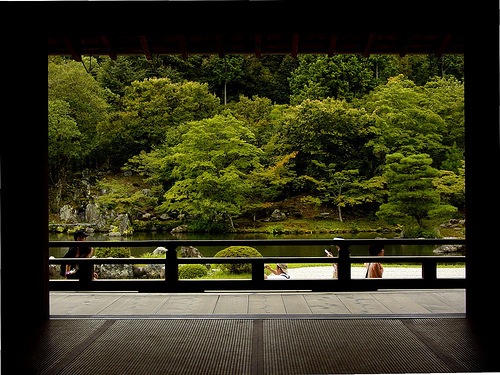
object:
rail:
[50, 239, 465, 294]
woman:
[365, 242, 386, 279]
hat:
[333, 236, 346, 241]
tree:
[122, 109, 297, 235]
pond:
[49, 231, 463, 266]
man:
[327, 236, 350, 280]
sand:
[267, 265, 469, 281]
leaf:
[291, 151, 298, 158]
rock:
[108, 213, 134, 234]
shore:
[50, 198, 470, 236]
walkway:
[47, 289, 467, 319]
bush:
[213, 246, 264, 274]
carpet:
[1, 318, 499, 373]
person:
[265, 262, 291, 280]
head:
[276, 263, 288, 274]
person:
[69, 229, 90, 280]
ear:
[76, 236, 80, 241]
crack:
[246, 294, 250, 315]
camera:
[265, 263, 269, 269]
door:
[41, 44, 472, 324]